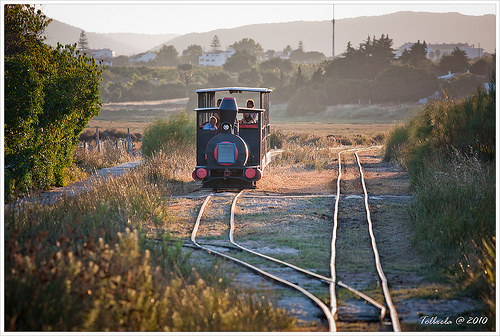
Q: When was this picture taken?
A: Daytime.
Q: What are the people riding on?
A: Train.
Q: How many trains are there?
A: One.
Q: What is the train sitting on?
A: Tracks.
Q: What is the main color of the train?
A: Black.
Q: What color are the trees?
A: Green.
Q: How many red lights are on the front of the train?
A: Two.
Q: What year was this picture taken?
A: 2010.